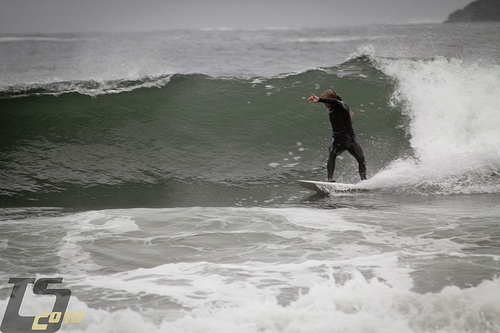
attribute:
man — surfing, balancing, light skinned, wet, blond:
[306, 88, 370, 182]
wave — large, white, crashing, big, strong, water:
[369, 51, 498, 192]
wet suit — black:
[327, 103, 368, 184]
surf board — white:
[300, 173, 361, 193]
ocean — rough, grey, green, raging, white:
[5, 2, 494, 327]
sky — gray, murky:
[4, 1, 456, 27]